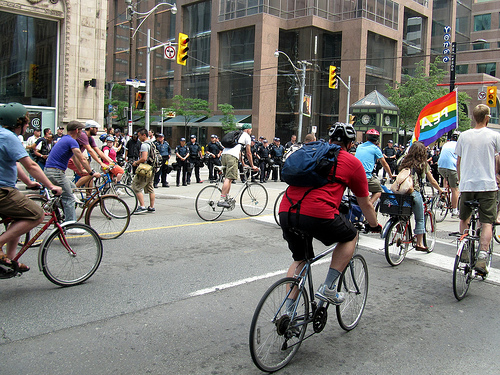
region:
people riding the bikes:
[11, 89, 476, 371]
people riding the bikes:
[222, 79, 472, 339]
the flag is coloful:
[382, 80, 472, 160]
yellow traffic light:
[328, 65, 338, 87]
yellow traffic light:
[176, 34, 189, 65]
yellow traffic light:
[484, 86, 495, 105]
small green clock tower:
[350, 86, 398, 145]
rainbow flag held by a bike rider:
[406, 88, 461, 150]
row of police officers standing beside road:
[145, 133, 406, 186]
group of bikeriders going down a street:
[0, 104, 497, 372]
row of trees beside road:
[103, 81, 240, 137]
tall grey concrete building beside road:
[1, 0, 111, 143]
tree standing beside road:
[385, 59, 467, 133]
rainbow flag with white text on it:
[407, 88, 459, 143]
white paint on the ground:
[188, 265, 293, 295]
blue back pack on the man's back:
[280, 140, 339, 191]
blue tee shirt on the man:
[47, 134, 78, 174]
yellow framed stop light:
[327, 63, 338, 90]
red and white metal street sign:
[164, 45, 174, 60]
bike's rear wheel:
[249, 275, 311, 370]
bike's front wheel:
[336, 254, 368, 331]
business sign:
[441, 25, 451, 68]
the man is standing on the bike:
[457, 102, 496, 277]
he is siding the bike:
[272, 200, 363, 282]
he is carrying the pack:
[293, 138, 354, 175]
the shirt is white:
[469, 146, 486, 172]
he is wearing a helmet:
[327, 118, 356, 148]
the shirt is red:
[312, 186, 329, 208]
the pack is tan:
[393, 168, 412, 188]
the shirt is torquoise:
[361, 149, 369, 165]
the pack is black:
[226, 127, 238, 144]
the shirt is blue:
[55, 147, 67, 159]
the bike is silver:
[297, 245, 355, 307]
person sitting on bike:
[2, 103, 102, 286]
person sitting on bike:
[249, 122, 382, 370]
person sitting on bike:
[68, 120, 138, 215]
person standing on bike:
[194, 118, 269, 222]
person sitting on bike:
[381, 140, 439, 266]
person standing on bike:
[450, 104, 497, 298]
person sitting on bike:
[354, 128, 394, 234]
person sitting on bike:
[275, 135, 318, 225]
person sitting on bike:
[431, 130, 462, 219]